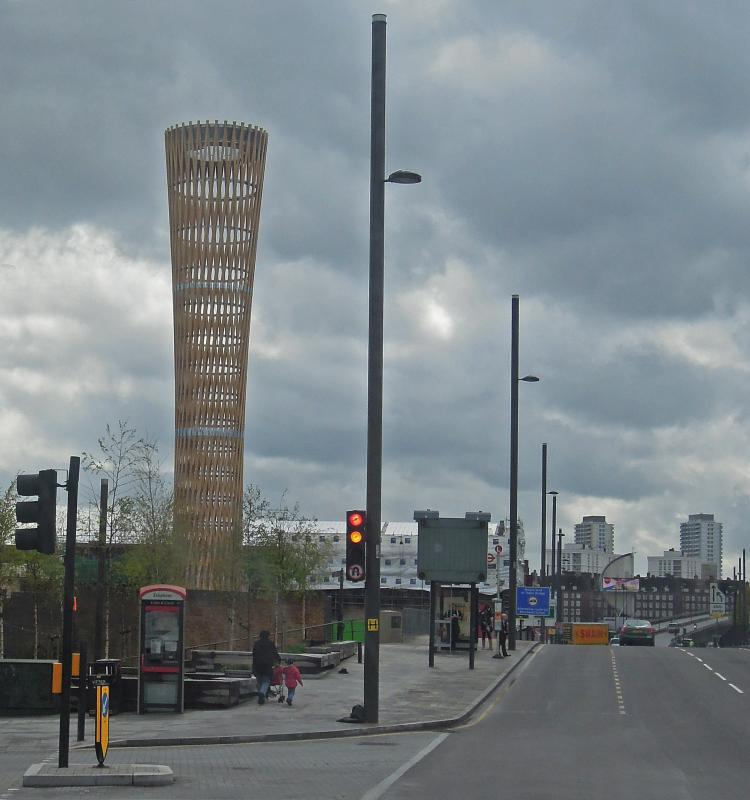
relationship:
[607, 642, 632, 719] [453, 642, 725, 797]
line on road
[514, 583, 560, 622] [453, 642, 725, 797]
sign on road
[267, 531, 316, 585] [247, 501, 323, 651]
leaves on tree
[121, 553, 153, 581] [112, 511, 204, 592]
leaves on tree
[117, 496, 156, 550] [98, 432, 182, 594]
leaves on tree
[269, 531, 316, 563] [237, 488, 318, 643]
leaves on tree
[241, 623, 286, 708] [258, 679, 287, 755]
woman and child walking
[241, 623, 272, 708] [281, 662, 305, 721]
woman pushing stroller with child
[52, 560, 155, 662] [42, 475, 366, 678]
leaves on tree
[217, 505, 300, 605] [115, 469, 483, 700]
leaves on tree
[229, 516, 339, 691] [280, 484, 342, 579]
leaves on tree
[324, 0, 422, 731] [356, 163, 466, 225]
pole with fixtures